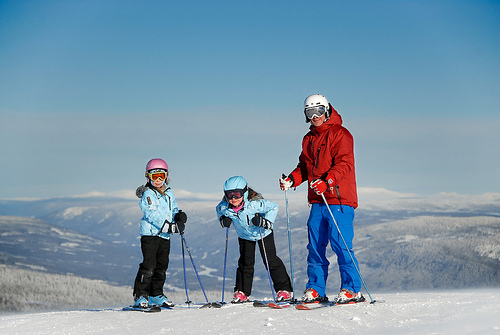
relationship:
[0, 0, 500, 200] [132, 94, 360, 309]
sky behind adult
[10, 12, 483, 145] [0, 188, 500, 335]
sky above mountain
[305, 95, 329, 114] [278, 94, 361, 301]
helmet on man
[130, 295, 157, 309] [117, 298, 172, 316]
shoe on ski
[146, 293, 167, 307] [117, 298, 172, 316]
shoe on ski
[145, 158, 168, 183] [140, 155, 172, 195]
helmet on head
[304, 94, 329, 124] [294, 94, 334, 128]
helmet on head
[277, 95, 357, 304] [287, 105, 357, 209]
adult on coat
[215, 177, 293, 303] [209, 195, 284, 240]
child wearing jacket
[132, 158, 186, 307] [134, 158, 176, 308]
girl wearing pants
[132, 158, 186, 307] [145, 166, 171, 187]
girl wearing goggles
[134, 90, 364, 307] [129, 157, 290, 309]
adult with children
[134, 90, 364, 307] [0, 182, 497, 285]
adult skiing on mountain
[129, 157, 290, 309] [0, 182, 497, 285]
children skiing on mountain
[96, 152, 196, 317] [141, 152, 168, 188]
girl wearing helmet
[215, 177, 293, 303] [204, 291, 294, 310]
child wearing skis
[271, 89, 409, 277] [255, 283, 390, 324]
adult on skis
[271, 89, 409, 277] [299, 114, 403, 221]
adult wearing jacket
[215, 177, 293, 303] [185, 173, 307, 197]
child wearing helmet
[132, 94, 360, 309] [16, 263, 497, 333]
adult on mountain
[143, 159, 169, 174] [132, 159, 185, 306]
pink helmet on girl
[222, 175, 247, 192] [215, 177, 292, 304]
helmet on child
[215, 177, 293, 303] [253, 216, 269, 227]
child wearing glove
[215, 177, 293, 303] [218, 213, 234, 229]
child wearing glove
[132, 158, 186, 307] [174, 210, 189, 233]
girl wearing glove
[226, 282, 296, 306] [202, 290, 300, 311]
pink boots on skis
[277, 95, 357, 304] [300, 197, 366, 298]
adult wearing pants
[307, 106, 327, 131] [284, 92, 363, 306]
face of man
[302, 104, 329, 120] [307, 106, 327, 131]
goggles on face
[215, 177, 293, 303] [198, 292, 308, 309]
child on skis